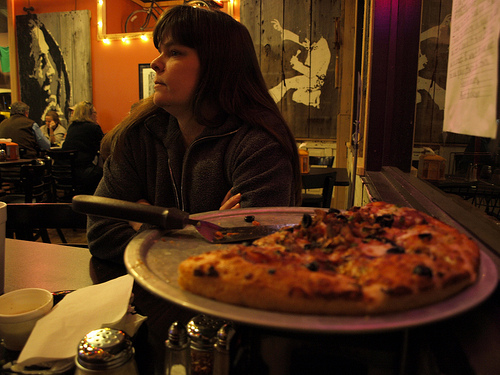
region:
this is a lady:
[118, 15, 259, 171]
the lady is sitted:
[107, 3, 267, 193]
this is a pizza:
[291, 203, 431, 295]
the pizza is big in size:
[302, 220, 423, 310]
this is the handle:
[78, 186, 180, 231]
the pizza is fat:
[221, 243, 310, 294]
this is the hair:
[213, 38, 257, 107]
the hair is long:
[218, 54, 260, 100]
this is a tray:
[124, 240, 170, 286]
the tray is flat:
[128, 238, 168, 287]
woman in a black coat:
[83, 5, 298, 266]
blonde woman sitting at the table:
[55, 99, 101, 173]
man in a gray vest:
[1, 100, 54, 158]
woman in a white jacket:
[38, 111, 65, 146]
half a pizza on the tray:
[126, 203, 496, 332]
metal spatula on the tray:
[73, 192, 300, 247]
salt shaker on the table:
[163, 321, 189, 373]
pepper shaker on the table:
[211, 323, 241, 374]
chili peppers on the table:
[185, 314, 223, 373]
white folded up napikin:
[18, 274, 140, 372]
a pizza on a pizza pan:
[174, 141, 484, 317]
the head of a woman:
[136, 11, 305, 111]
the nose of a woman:
[146, 50, 167, 80]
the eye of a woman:
[159, 37, 207, 62]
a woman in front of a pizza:
[86, 28, 368, 254]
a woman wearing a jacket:
[79, 27, 339, 258]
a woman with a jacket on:
[81, 50, 363, 275]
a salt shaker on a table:
[69, 317, 169, 369]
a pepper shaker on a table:
[181, 304, 251, 365]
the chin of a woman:
[146, 83, 188, 117]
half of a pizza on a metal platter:
[180, 194, 463, 328]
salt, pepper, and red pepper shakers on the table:
[153, 308, 233, 374]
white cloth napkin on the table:
[8, 266, 130, 373]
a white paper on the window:
[423, 6, 498, 142]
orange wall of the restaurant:
[97, 53, 125, 101]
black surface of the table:
[28, 246, 78, 277]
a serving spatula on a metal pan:
[68, 186, 295, 251]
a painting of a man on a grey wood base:
[4, 5, 101, 115]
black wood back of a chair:
[13, 199, 91, 237]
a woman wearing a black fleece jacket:
[84, 8, 304, 253]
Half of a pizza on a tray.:
[123, 193, 488, 339]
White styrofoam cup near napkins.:
[0, 280, 54, 365]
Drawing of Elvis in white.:
[267, 18, 330, 113]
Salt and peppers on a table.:
[165, 323, 245, 372]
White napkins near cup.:
[16, 282, 145, 362]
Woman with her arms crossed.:
[72, 5, 302, 280]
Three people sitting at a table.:
[7, 98, 107, 166]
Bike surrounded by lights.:
[92, 0, 229, 51]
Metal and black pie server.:
[70, 190, 296, 237]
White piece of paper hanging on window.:
[440, 0, 499, 149]